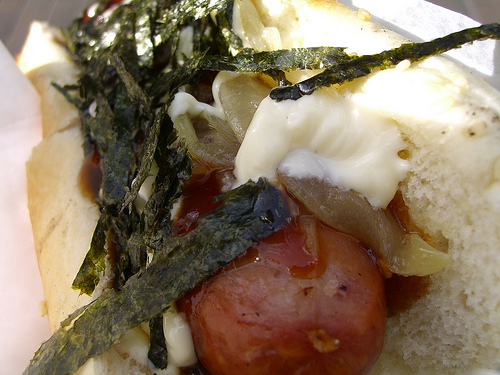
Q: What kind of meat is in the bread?
A: Hot dog.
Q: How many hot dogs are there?
A: One.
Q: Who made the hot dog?
A: Cook.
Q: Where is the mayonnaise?
A: On top of the hot dog.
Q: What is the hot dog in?
A: Bun.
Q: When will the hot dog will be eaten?
A: While it is warm.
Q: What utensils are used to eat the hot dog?
A: None.